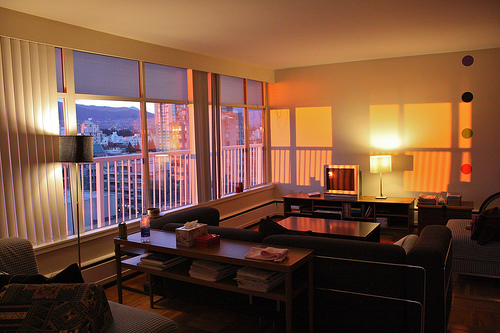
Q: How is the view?
A: Dim.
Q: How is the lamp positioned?
A: Against the wall.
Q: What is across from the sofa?
A: T.v.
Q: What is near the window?
A: Chair.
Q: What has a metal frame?
A: The sofa.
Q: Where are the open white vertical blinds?
A: On the window.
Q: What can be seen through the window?
A: A view of the city.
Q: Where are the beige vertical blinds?
A: On the window.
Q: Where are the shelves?
A: On the wooden sofa table.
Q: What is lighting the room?
A: A lamp.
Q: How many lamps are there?
A: 1.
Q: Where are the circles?
A: 4.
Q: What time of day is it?
A: Evening.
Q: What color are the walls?
A: White.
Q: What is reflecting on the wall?
A: The windows.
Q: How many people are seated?
A: 0.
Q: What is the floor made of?
A: Wood.